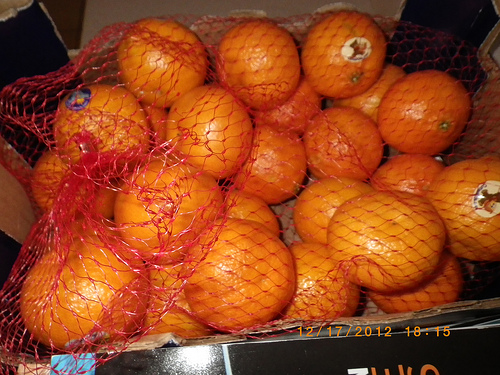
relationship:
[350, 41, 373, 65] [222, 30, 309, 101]
sticker on orange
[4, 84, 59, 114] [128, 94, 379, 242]
bag of oranges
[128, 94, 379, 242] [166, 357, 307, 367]
oranges in box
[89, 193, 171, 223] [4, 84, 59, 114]
hole in bag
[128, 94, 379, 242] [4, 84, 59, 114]
oranges in bag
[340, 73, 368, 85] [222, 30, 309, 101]
stem on orange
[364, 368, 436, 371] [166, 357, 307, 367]
letters on box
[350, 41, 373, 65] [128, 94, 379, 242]
sticker on oranges